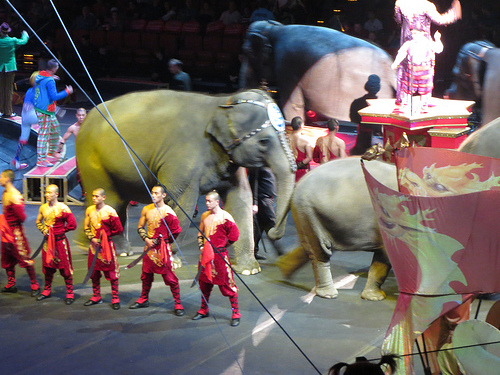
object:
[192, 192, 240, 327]
man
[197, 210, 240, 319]
clothes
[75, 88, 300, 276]
elephant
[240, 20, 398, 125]
elephant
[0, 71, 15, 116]
pants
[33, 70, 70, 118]
jacket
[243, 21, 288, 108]
shadow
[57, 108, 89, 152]
man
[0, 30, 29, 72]
jacket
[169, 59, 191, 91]
man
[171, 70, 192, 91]
suit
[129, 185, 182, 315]
people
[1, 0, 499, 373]
circus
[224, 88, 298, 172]
decoration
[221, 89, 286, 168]
head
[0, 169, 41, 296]
people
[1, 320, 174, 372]
ground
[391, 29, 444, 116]
people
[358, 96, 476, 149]
platform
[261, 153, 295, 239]
trunk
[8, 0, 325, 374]
wire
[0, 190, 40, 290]
uniform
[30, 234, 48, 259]
weapon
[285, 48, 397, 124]
light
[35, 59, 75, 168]
man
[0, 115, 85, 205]
table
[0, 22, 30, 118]
man